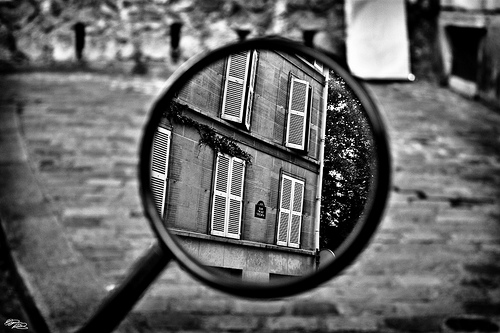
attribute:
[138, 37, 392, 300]
rear view mirror — reflecting, on car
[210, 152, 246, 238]
window — closed, picture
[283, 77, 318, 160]
window — slightly open, open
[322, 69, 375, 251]
plants — vining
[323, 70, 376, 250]
tree — hiding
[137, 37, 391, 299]
frame — round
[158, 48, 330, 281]
wall — on building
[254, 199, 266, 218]
sign — picture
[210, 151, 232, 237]
shutter — white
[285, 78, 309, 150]
shutter — open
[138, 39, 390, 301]
mirror — picture, black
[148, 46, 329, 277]
building — picture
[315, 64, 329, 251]
gutter spout — picture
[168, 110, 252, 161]
plant — growing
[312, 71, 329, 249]
pole — picture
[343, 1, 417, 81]
object — white